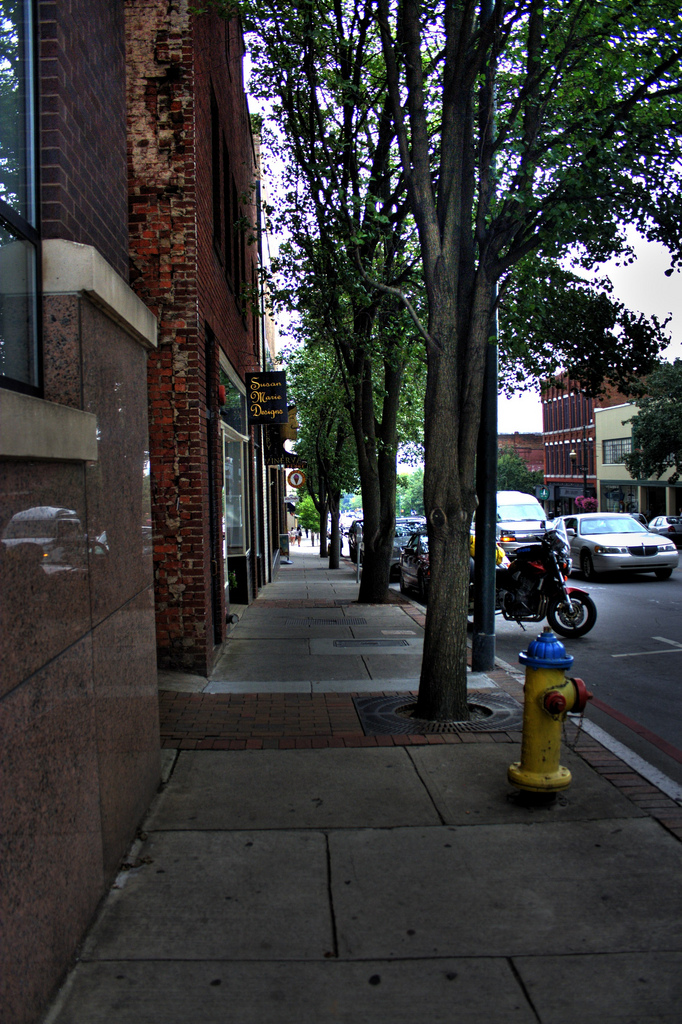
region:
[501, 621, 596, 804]
yellow, blue and red fire hydrant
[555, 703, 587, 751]
chain on front of fire hydrant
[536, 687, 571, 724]
red lug on side of fire hydrant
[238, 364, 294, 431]
black and yellow sign on side of business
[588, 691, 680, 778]
red line drawn on street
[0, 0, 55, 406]
window on front of building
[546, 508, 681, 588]
car driving down street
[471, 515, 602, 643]
motorcycle parked next to sidewalk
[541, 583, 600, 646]
front wheel of motorcycle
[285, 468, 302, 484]
the red and white circle sign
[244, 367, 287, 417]
the gold and black sign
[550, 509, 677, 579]
the white car driving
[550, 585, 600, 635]
the front wheel of the bike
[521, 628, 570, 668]
the blue top of the hydrant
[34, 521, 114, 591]
the reflection of the car on the wall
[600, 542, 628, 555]
the headlight of the car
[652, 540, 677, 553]
the headlight of the car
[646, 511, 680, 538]
the parked car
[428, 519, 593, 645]
bike parked on the street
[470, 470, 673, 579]
cars on the road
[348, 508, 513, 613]
cars parked on the street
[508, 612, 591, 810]
a yellow fire hydrant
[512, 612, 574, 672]
blue top of hydrant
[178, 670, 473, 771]
red patch of bricks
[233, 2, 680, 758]
a row of trees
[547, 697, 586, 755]
chain on the hydrant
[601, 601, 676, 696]
lines on the street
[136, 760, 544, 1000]
spots on the sidewalk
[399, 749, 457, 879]
A person eating a orange.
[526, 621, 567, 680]
Top hydrant is blue.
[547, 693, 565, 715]
Cap on nozzle is red.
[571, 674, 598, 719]
Cap on nozzle is red.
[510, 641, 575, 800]
Fire hydrant is mostly yellow.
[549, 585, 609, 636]
Front wheel on bike is black.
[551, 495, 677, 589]
Silver car driving on road.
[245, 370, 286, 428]
Black sign with yellow words attached to building.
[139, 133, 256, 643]
Large reddish brown brick building.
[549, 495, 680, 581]
a car on a street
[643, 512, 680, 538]
a car on a street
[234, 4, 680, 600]
Leafy green trees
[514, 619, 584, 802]
A yellow, blue, and red fire hydrant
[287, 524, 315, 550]
people on the sidewalk.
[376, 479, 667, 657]
Vehicles on the road.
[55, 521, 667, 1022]
The sidewalk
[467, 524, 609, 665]
a parked motorcycle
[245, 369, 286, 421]
A black and yellow shop sign on the side of a building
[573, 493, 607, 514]
A hanging flower basket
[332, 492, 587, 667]
Vehicles parked along the sides of the road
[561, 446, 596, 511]
A street light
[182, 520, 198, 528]
A brick in a building.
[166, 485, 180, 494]
A brick in a building.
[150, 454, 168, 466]
A brick in a building.